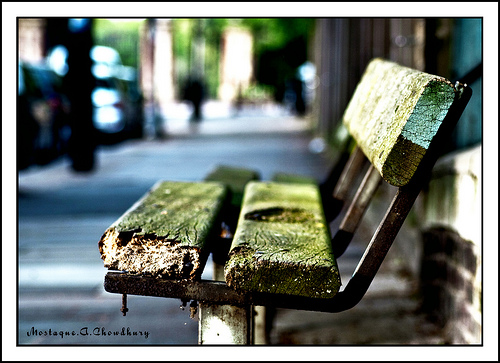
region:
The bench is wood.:
[111, 52, 428, 301]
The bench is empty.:
[134, 55, 428, 333]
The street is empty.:
[32, 167, 107, 299]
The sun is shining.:
[100, 35, 440, 349]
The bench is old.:
[125, 71, 439, 326]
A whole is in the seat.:
[248, 201, 343, 255]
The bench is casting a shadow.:
[336, 222, 489, 340]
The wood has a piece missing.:
[80, 204, 203, 307]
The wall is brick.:
[404, 217, 482, 319]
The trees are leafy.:
[172, 24, 227, 89]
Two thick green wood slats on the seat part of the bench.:
[98, 175, 341, 297]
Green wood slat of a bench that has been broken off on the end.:
[99, 176, 231, 287]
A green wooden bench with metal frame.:
[99, 55, 476, 348]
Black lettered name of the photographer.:
[23, 324, 151, 341]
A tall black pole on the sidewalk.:
[65, 15, 101, 172]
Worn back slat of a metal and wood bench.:
[341, 59, 456, 186]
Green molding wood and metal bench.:
[98, 60, 474, 347]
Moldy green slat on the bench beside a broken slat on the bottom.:
[225, 178, 341, 297]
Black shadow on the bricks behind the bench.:
[411, 222, 479, 332]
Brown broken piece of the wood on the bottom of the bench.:
[97, 230, 202, 285]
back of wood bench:
[337, 59, 451, 155]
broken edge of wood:
[97, 222, 204, 286]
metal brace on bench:
[352, 206, 406, 289]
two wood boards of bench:
[121, 173, 319, 290]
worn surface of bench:
[249, 229, 309, 266]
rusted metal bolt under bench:
[105, 293, 136, 323]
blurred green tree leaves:
[257, 18, 287, 50]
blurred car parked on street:
[94, 64, 141, 137]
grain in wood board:
[276, 241, 326, 268]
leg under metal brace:
[192, 295, 256, 345]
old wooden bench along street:
[127, 43, 449, 304]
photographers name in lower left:
[18, 322, 159, 349]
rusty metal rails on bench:
[306, 140, 416, 302]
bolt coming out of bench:
[102, 289, 142, 319]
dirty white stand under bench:
[192, 297, 289, 353]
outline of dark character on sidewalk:
[162, 67, 227, 130]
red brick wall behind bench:
[399, 227, 497, 329]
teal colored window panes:
[433, 31, 498, 114]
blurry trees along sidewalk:
[160, 20, 292, 96]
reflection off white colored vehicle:
[62, 36, 139, 133]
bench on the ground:
[104, 56, 448, 311]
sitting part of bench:
[142, 166, 337, 311]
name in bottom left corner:
[23, 319, 160, 345]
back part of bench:
[341, 41, 458, 187]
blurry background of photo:
[196, 58, 294, 122]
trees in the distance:
[261, 26, 291, 49]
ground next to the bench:
[35, 280, 82, 315]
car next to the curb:
[27, 68, 83, 134]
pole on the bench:
[361, 209, 427, 261]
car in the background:
[91, 71, 145, 141]